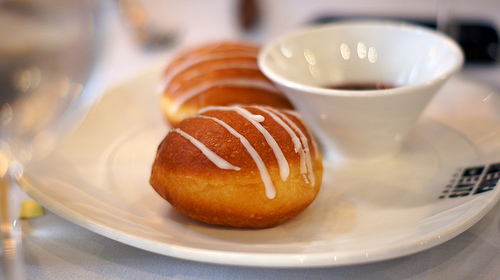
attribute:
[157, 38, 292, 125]
pastry — delicious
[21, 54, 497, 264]
plate — clean, white, crumbless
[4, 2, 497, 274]
table — white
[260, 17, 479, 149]
cup — small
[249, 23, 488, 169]
bowl — small, white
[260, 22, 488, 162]
cup — white, small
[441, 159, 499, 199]
logo — black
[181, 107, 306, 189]
frosting — white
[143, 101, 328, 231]
pastry — delicious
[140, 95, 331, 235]
doughnuts — puffy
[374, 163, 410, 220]
dish — small, round, white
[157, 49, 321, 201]
frosting — white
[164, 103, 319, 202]
stripes — white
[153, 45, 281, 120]
stripes — white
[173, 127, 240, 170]
icing — white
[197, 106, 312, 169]
frosting — white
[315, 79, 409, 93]
sauce — brown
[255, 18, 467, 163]
cup — small, white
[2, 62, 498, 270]
plate — white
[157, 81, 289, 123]
icing — white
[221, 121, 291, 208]
icing — white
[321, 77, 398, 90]
liquid — brown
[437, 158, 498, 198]
writing — black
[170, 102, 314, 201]
frosting — white